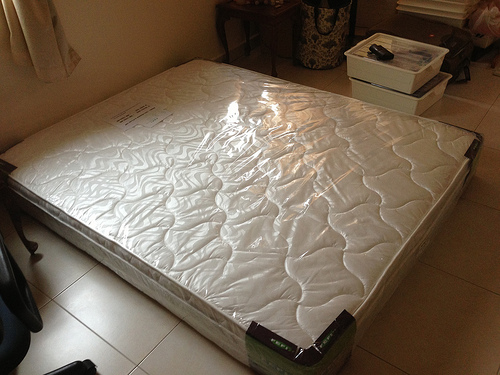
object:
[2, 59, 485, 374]
bed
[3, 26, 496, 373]
floor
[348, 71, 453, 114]
box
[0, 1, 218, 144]
wall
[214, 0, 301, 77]
table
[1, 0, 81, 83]
drapery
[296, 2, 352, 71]
bag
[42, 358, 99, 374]
leg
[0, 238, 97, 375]
chair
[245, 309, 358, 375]
edge protector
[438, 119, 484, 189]
edge protector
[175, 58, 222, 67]
edge protector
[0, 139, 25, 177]
edge protector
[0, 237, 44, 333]
chair arm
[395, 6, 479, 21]
tray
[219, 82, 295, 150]
reflection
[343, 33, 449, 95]
containers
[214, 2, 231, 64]
legs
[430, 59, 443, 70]
handle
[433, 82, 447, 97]
handle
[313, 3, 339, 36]
handle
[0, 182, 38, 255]
stool